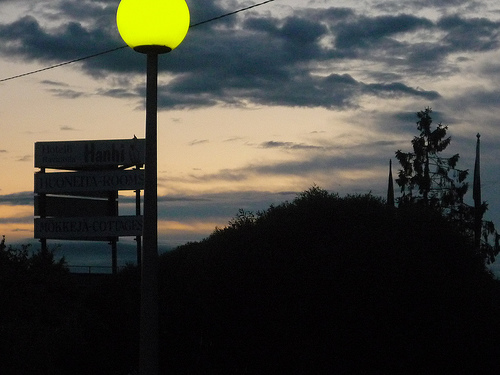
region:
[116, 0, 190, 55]
a yellow street light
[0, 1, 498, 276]
a cloudy evening sky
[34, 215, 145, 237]
a street name sign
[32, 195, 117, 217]
a street name sign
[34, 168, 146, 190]
a street name sign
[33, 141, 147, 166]
a street name sign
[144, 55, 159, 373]
a tall metal pole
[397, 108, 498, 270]
a tall tree in distance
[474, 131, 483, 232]
a still flag on pole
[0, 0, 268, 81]
an overhead electrical wire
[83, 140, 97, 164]
black letter on sign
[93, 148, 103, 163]
black letter on sign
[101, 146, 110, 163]
black letter on sign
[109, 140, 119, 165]
black letter on sign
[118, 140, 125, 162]
black letter on sign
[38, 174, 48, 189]
black letter on sign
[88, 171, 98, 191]
black letter on sign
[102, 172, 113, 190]
black letter on sign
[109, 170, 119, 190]
black letter on sign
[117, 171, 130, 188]
black letter on sign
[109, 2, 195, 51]
The yellow light out side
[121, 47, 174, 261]
The pole that is holding up the light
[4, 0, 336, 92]
The electrical line in the top corner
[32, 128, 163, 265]
The silouhette of the street signs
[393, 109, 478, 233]
The siloutte of the tree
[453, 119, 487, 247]
The silouhette of the cactus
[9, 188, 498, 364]
A small hill with grass on it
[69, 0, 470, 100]
Clouds that are in the sky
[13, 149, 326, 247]
The orange area of the sky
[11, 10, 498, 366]
A dark outdoor area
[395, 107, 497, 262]
A tree looking sharp against the sky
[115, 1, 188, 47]
A yellow street light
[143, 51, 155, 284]
Pole of the street light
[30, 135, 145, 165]
A board displaying the name 'Hotel Hanhi'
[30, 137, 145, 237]
Advertisement board of a hotel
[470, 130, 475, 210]
A flag on a post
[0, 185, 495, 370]
A hill top against the sky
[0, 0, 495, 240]
Sky full of dark clouds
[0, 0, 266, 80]
An electrical cable going overhead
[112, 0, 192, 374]
a yellow globe light on a post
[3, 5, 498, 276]
orange and blue sunset sky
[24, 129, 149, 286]
signs attached to posts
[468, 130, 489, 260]
a flag on a pole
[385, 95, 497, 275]
a shrub is silhouetted against the sky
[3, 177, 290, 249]
purple streaks in a sunset sky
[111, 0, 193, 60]
globe is glowing yellow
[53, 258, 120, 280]
a railing in the background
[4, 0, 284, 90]
power cable in the sky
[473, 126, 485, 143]
knob on the top of a flag pole